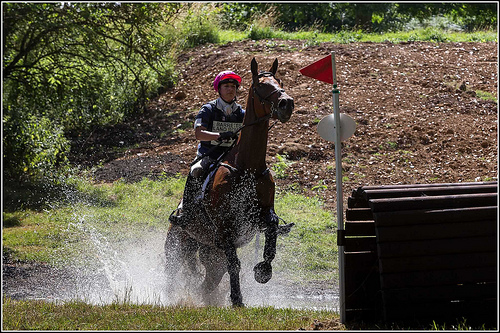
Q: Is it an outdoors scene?
A: Yes, it is outdoors.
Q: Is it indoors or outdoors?
A: It is outdoors.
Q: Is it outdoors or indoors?
A: It is outdoors.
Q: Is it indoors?
A: No, it is outdoors.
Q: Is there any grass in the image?
A: Yes, there is grass.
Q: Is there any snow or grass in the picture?
A: Yes, there is grass.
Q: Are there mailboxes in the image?
A: No, there are no mailboxes.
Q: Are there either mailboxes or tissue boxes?
A: No, there are no mailboxes or tissue boxes.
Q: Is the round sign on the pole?
A: Yes, the sign is on the pole.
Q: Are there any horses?
A: Yes, there is a horse.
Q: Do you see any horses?
A: Yes, there is a horse.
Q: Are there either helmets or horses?
A: Yes, there is a horse.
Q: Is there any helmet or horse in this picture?
A: Yes, there is a horse.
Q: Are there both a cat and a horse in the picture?
A: No, there is a horse but no cats.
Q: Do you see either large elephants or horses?
A: Yes, there is a large horse.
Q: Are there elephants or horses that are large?
A: Yes, the horse is large.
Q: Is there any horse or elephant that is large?
A: Yes, the horse is large.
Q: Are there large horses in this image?
A: Yes, there is a large horse.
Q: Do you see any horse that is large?
A: Yes, there is a horse that is large.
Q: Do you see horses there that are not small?
A: Yes, there is a large horse.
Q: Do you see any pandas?
A: No, there are no pandas.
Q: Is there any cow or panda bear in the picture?
A: No, there are no pandas or cows.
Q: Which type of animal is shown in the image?
A: The animal is a horse.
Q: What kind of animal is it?
A: The animal is a horse.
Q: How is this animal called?
A: This is a horse.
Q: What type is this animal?
A: This is a horse.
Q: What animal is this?
A: This is a horse.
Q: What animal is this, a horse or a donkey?
A: This is a horse.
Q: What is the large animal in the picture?
A: The animal is a horse.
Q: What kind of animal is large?
A: The animal is a horse.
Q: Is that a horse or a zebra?
A: That is a horse.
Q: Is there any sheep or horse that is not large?
A: No, there is a horse but it is large.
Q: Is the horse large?
A: Yes, the horse is large.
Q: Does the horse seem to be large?
A: Yes, the horse is large.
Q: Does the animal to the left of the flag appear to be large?
A: Yes, the horse is large.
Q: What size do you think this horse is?
A: The horse is large.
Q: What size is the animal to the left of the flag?
A: The horse is large.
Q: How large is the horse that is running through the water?
A: The horse is large.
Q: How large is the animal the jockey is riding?
A: The horse is large.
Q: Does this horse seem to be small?
A: No, the horse is large.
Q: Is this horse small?
A: No, the horse is large.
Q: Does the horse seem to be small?
A: No, the horse is large.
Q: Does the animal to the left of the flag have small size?
A: No, the horse is large.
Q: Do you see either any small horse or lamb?
A: No, there is a horse but it is large.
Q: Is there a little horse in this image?
A: No, there is a horse but it is large.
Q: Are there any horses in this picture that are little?
A: No, there is a horse but it is large.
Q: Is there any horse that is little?
A: No, there is a horse but it is large.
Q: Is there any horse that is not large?
A: No, there is a horse but it is large.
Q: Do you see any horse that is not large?
A: No, there is a horse but it is large.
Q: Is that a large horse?
A: Yes, that is a large horse.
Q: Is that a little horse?
A: No, that is a large horse.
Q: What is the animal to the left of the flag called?
A: The animal is a horse.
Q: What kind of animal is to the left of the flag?
A: The animal is a horse.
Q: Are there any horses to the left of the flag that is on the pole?
A: Yes, there is a horse to the left of the flag.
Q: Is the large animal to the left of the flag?
A: Yes, the horse is to the left of the flag.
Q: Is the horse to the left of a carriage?
A: No, the horse is to the left of the flag.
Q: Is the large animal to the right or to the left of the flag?
A: The horse is to the left of the flag.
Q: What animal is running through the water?
A: The horse is running through the water.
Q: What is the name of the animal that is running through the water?
A: The animal is a horse.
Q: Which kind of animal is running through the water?
A: The animal is a horse.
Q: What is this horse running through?
A: The horse is running through the water.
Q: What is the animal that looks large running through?
A: The horse is running through the water.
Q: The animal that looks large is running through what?
A: The horse is running through the water.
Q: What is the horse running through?
A: The horse is running through the water.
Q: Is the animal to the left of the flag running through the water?
A: Yes, the horse is running through the water.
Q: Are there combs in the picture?
A: No, there are no combs.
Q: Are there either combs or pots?
A: No, there are no combs or pots.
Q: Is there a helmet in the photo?
A: Yes, there is a helmet.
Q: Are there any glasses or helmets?
A: Yes, there is a helmet.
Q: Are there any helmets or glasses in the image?
A: Yes, there is a helmet.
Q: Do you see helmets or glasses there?
A: Yes, there is a helmet.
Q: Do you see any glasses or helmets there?
A: Yes, there is a helmet.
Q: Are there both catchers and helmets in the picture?
A: No, there is a helmet but no catchers.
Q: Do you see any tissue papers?
A: No, there are no tissue papers.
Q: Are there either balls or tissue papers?
A: No, there are no tissue papers or balls.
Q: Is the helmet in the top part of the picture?
A: Yes, the helmet is in the top of the image.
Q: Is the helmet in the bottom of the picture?
A: No, the helmet is in the top of the image.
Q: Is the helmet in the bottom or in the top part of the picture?
A: The helmet is in the top of the image.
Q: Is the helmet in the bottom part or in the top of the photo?
A: The helmet is in the top of the image.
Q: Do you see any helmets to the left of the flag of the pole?
A: Yes, there is a helmet to the left of the flag.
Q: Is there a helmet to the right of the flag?
A: No, the helmet is to the left of the flag.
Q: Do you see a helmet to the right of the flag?
A: No, the helmet is to the left of the flag.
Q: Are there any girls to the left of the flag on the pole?
A: No, there is a helmet to the left of the flag.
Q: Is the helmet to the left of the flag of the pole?
A: Yes, the helmet is to the left of the flag.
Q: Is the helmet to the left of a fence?
A: No, the helmet is to the left of the flag.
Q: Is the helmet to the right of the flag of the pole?
A: No, the helmet is to the left of the flag.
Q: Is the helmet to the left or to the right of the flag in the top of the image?
A: The helmet is to the left of the flag.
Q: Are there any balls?
A: No, there are no balls.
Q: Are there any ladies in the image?
A: No, there are no ladies.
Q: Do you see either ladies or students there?
A: No, there are no ladies or students.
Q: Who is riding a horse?
A: The jockey is riding a horse.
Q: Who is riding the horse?
A: The jockey is riding a horse.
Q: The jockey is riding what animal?
A: The jockey is riding a horse.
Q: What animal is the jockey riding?
A: The jockey is riding a horse.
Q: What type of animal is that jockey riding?
A: The jockey is riding a horse.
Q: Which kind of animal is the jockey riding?
A: The jockey is riding a horse.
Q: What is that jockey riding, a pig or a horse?
A: The jockey is riding a horse.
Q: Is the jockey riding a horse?
A: Yes, the jockey is riding a horse.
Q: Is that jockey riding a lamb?
A: No, the jockey is riding a horse.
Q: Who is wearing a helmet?
A: The jockey is wearing a helmet.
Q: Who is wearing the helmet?
A: The jockey is wearing a helmet.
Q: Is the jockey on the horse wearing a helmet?
A: Yes, the jockey is wearing a helmet.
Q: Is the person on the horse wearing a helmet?
A: Yes, the jockey is wearing a helmet.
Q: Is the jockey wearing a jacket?
A: No, the jockey is wearing a helmet.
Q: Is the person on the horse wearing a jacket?
A: No, the jockey is wearing a helmet.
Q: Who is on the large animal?
A: The jockey is on the horse.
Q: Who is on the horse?
A: The jockey is on the horse.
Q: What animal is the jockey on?
A: The jockey is on the horse.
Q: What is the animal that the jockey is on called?
A: The animal is a horse.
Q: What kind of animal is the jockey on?
A: The jockey is on the horse.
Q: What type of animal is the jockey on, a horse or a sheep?
A: The jockey is on a horse.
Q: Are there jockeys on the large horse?
A: Yes, there is a jockey on the horse.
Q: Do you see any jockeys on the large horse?
A: Yes, there is a jockey on the horse.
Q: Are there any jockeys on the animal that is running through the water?
A: Yes, there is a jockey on the horse.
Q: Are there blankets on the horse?
A: No, there is a jockey on the horse.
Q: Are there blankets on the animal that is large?
A: No, there is a jockey on the horse.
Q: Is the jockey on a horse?
A: Yes, the jockey is on a horse.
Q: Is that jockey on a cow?
A: No, the jockey is on a horse.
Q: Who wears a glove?
A: The jockey wears a glove.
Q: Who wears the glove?
A: The jockey wears a glove.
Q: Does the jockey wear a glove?
A: Yes, the jockey wears a glove.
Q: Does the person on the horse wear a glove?
A: Yes, the jockey wears a glove.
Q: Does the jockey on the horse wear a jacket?
A: No, the jockey wears a glove.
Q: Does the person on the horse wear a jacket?
A: No, the jockey wears a glove.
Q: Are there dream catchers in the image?
A: No, there are no dream catchers.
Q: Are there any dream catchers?
A: No, there are no dream catchers.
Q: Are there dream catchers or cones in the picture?
A: No, there are no dream catchers or cones.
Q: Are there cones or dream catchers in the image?
A: No, there are no dream catchers or cones.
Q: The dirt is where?
A: The dirt is on the hill.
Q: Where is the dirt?
A: The dirt is on the hill.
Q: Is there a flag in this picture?
A: Yes, there is a flag.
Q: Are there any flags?
A: Yes, there is a flag.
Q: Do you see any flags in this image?
A: Yes, there is a flag.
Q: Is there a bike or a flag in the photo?
A: Yes, there is a flag.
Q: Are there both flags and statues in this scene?
A: No, there is a flag but no statues.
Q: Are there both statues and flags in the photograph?
A: No, there is a flag but no statues.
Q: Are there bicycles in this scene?
A: No, there are no bicycles.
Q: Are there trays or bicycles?
A: No, there are no bicycles or trays.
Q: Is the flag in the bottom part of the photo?
A: No, the flag is in the top of the image.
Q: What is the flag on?
A: The flag is on the pole.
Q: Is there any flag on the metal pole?
A: Yes, there is a flag on the pole.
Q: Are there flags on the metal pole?
A: Yes, there is a flag on the pole.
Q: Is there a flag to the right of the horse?
A: Yes, there is a flag to the right of the horse.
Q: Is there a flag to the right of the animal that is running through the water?
A: Yes, there is a flag to the right of the horse.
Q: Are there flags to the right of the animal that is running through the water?
A: Yes, there is a flag to the right of the horse.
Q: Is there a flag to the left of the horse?
A: No, the flag is to the right of the horse.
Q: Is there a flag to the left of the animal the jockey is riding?
A: No, the flag is to the right of the horse.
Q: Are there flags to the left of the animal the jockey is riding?
A: No, the flag is to the right of the horse.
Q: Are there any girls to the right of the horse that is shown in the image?
A: No, there is a flag to the right of the horse.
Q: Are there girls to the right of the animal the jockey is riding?
A: No, there is a flag to the right of the horse.